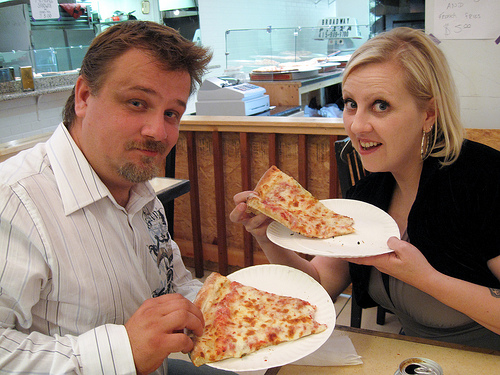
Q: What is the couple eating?
A: Pizza.